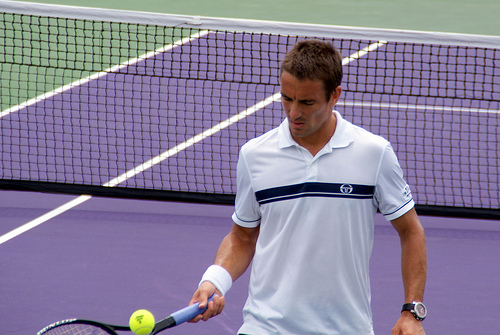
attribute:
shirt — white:
[225, 135, 405, 318]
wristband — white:
[200, 262, 233, 291]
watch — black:
[402, 299, 429, 320]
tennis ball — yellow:
[126, 309, 157, 333]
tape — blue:
[174, 299, 214, 325]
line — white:
[13, 207, 57, 234]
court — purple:
[48, 222, 153, 295]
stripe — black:
[255, 179, 374, 204]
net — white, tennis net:
[10, 2, 224, 169]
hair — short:
[283, 41, 340, 94]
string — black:
[112, 26, 152, 61]